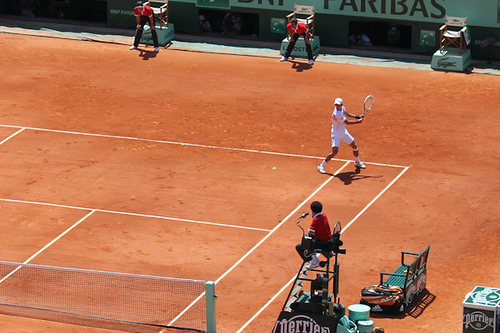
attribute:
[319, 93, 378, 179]
player — wearing white, holding racket, in white, swinging, on court, wearing shorts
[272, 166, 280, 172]
ball — yellow, green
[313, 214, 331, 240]
shirt — red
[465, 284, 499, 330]
water — advertisement, in container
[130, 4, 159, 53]
person — bending, wearing shirt, near wall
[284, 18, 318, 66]
man — wearing shirt, wearing hat, near wall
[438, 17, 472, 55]
seat — empty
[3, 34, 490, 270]
court — red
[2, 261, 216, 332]
net — on court, on top of court, white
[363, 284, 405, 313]
bag — black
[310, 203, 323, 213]
hair — black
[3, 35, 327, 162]
dirt — brown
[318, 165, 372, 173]
sneakers — white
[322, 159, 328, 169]
sock — white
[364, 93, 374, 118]
racket — in hand, white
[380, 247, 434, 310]
bench — green, a green bench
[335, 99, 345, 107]
hat — on player, white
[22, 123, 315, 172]
line — white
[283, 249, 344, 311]
chair — tall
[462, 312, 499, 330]
logo — on box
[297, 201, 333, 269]
commentator — sitting, in shirt, wearing shirt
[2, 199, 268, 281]
lines — on top of court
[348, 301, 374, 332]
barrels — green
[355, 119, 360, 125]
wristband — red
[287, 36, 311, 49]
hands — on knees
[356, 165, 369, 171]
shoe — white